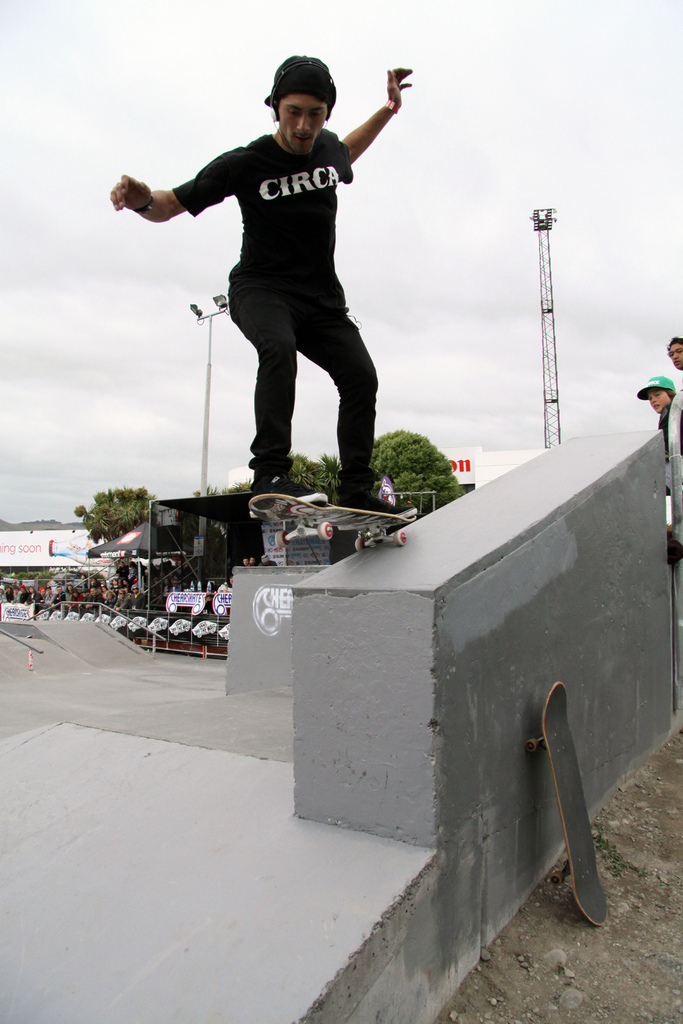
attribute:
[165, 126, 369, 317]
shirt — black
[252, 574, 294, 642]
letters — white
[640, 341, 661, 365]
hair — dark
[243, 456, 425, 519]
tennis shoes — black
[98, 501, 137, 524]
leaves — green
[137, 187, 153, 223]
watch band — black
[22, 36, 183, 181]
clouds — white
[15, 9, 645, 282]
sky — blue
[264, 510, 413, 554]
wheels — red, white